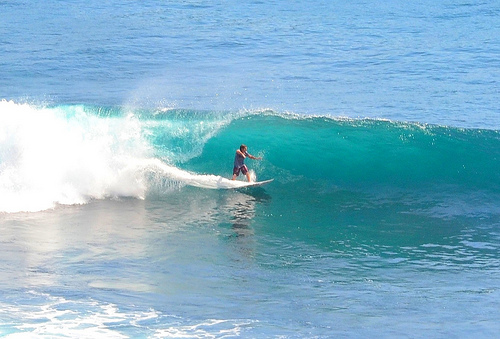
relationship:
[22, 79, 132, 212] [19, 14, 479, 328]
water in ocean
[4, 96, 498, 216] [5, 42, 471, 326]
wave in ocean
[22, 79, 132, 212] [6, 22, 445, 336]
water in ocean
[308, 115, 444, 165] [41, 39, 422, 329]
waves in ocean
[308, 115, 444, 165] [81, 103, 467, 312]
waves in ocean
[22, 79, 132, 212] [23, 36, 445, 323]
water in ocean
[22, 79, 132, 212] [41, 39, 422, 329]
water in ocean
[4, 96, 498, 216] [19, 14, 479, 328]
wave in ocean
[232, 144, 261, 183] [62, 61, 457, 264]
guy riding a wave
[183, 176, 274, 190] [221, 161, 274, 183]
board under person's feet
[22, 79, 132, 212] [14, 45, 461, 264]
water from wave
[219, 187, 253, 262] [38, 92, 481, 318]
reflection in water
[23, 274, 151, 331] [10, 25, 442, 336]
foam on water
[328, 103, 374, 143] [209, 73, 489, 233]
part of wave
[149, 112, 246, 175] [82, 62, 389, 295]
part of wave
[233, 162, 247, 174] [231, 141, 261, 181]
shorts on surfer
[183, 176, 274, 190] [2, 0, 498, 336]
board in water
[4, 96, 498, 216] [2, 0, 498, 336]
wave in water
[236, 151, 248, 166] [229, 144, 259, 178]
shirt on man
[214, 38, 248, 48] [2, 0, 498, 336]
ripple of water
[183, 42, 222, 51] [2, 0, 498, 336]
ripple of water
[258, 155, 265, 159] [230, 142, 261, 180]
hand of man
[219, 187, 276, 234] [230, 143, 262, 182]
reflection of man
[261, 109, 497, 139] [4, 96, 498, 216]
top of wave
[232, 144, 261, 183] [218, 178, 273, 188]
guy standing on a board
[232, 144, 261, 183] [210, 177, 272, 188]
guy standing on a board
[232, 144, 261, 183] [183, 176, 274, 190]
guy standing on a board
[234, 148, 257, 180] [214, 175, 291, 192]
guy on surf board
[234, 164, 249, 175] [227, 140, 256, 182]
shorts on man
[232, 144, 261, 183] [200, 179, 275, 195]
guy standing on board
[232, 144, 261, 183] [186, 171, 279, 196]
guy standing on surfboard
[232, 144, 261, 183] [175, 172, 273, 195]
guy standing on surfboard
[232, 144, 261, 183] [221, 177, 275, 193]
guy rides surfboard